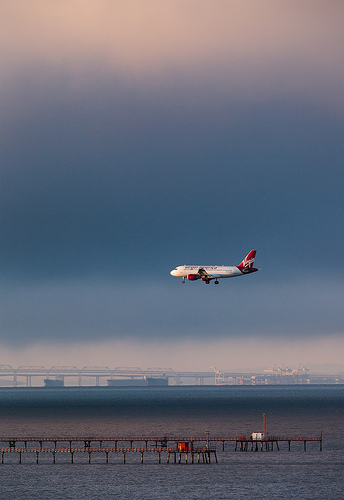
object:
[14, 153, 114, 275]
blue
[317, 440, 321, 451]
support beam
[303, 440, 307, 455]
support beam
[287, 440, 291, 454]
support beam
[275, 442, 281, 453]
support beam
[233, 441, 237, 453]
support beam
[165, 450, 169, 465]
support beam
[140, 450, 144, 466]
support beam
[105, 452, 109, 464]
support beam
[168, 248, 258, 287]
jet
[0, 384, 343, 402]
wall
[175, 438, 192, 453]
box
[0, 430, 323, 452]
docks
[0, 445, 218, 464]
dock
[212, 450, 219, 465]
post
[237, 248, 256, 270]
wing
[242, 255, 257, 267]
stripe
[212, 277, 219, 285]
landing wheels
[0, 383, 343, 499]
ocean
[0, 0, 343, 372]
cloudy